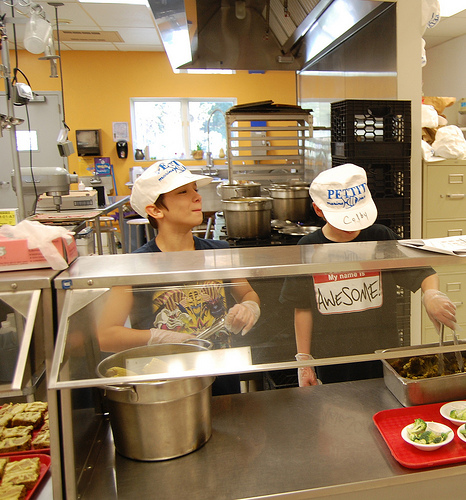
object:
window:
[128, 93, 243, 162]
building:
[63, 22, 375, 244]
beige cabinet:
[422, 159, 466, 347]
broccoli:
[409, 417, 444, 444]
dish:
[401, 420, 455, 451]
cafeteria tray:
[370, 400, 465, 470]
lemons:
[405, 414, 451, 447]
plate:
[397, 416, 457, 454]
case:
[54, 246, 465, 497]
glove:
[421, 289, 458, 335]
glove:
[294, 353, 322, 388]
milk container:
[329, 97, 412, 160]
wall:
[0, 48, 304, 205]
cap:
[130, 160, 213, 219]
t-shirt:
[278, 223, 437, 385]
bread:
[0, 401, 50, 455]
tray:
[0, 401, 52, 500]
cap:
[309, 162, 378, 231]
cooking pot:
[95, 343, 212, 462]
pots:
[216, 178, 313, 242]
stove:
[203, 210, 322, 249]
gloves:
[147, 300, 260, 349]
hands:
[146, 300, 259, 346]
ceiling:
[139, 20, 148, 31]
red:
[377, 411, 396, 435]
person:
[98, 158, 262, 397]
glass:
[61, 264, 464, 380]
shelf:
[46, 259, 464, 388]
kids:
[95, 157, 455, 401]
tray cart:
[222, 101, 317, 192]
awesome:
[318, 280, 379, 310]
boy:
[279, 163, 457, 388]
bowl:
[401, 421, 455, 452]